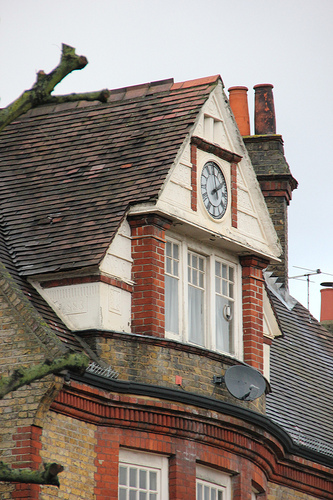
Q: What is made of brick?
A: A large building.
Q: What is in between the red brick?
A: Brown bricks.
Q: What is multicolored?
A: The rooftop.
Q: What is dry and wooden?
A: The pole.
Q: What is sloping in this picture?
A: A long roof.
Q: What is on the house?
A: Brickwork.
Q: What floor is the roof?
A: Second story.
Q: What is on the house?
A: Satellite dish.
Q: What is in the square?
A: Stone building.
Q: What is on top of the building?
A: Chimney.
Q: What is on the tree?
A: Green branches.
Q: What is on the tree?
A: Cut branch.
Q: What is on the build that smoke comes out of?
A: Chimney.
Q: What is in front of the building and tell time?
A: Clock.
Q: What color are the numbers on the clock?
A: Black.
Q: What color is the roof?
A: Black.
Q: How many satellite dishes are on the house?
A: One.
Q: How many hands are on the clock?
A: Two.